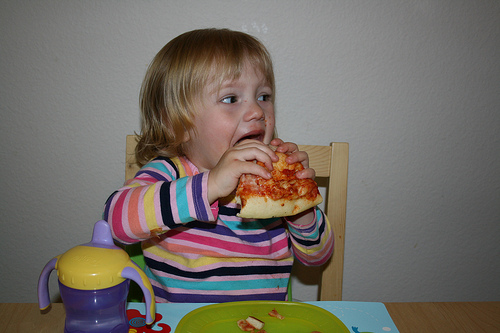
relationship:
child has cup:
[101, 26, 368, 314] [18, 215, 180, 332]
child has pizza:
[101, 26, 368, 314] [232, 133, 329, 223]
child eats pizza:
[101, 26, 368, 314] [232, 133, 329, 223]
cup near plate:
[18, 215, 180, 332] [167, 297, 366, 332]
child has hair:
[101, 26, 368, 314] [115, 18, 307, 174]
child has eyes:
[101, 26, 368, 314] [207, 85, 274, 112]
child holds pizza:
[101, 26, 368, 314] [232, 133, 329, 223]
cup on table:
[18, 215, 180, 332] [4, 301, 500, 331]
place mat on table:
[115, 290, 404, 332] [4, 301, 500, 331]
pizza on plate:
[232, 133, 329, 223] [167, 297, 366, 332]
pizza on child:
[232, 133, 329, 223] [101, 26, 368, 314]